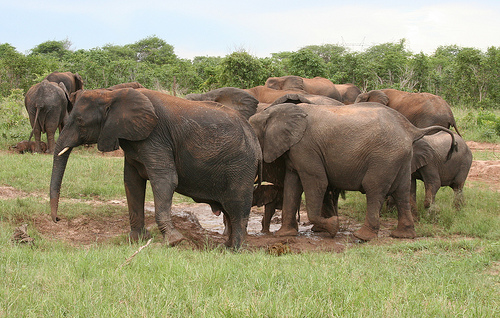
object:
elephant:
[42, 81, 264, 251]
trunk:
[45, 120, 79, 223]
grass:
[0, 104, 499, 317]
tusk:
[56, 145, 70, 158]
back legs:
[223, 178, 254, 255]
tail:
[254, 131, 267, 199]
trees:
[459, 38, 500, 109]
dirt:
[0, 137, 499, 255]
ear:
[97, 88, 159, 153]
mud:
[0, 143, 500, 256]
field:
[0, 0, 500, 316]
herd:
[14, 69, 473, 253]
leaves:
[1, 54, 29, 72]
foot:
[159, 225, 185, 245]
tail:
[412, 124, 460, 163]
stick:
[118, 234, 153, 270]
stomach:
[175, 159, 221, 204]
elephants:
[237, 101, 458, 238]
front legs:
[124, 151, 147, 249]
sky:
[0, 0, 500, 58]